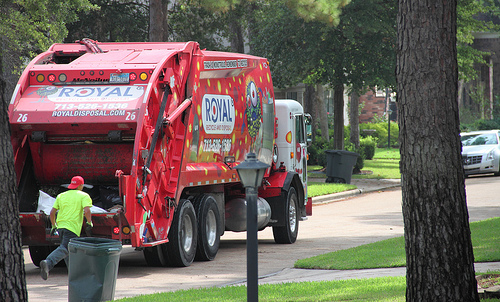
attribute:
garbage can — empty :
[68, 236, 123, 300]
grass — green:
[115, 274, 497, 299]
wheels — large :
[171, 187, 299, 257]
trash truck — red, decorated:
[8, 35, 313, 267]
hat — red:
[59, 174, 86, 189]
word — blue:
[197, 88, 243, 129]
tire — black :
[273, 185, 306, 257]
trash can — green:
[314, 144, 367, 196]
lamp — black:
[224, 139, 288, 300]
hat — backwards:
[57, 160, 97, 192]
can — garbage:
[64, 236, 128, 300]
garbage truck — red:
[7, 36, 312, 266]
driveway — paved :
[249, 259, 493, 288]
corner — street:
[313, 179, 419, 209]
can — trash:
[63, 229, 129, 300]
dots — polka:
[183, 54, 256, 180]